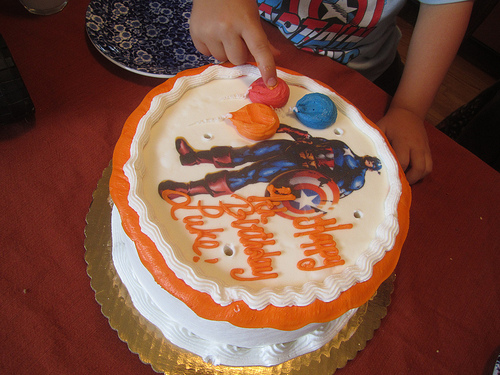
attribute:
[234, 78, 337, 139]
icing — red, orange, blue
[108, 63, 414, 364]
cake — orange, white, 9 inch round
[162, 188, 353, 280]
writing — orange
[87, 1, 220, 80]
plate — blue, black, white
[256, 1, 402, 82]
shirt — white, blue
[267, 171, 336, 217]
battle shield — red, blue, white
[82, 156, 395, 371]
platter — gold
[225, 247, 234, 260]
hole — without candle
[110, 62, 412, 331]
border — orange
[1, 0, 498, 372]
table cloth — red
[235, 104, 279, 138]
ball of frosting — orange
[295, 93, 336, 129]
ball of frosting — blue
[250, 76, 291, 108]
ball of frosting — red